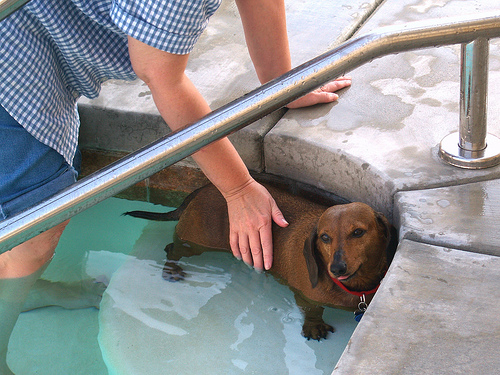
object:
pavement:
[73, 0, 499, 373]